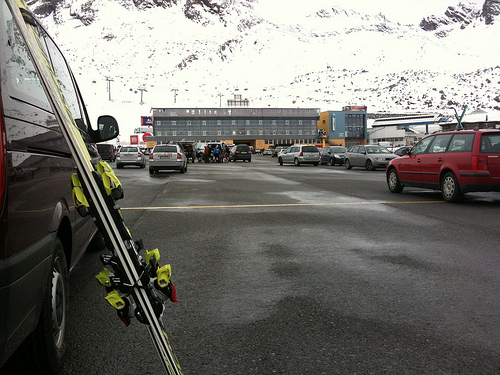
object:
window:
[447, 132, 476, 152]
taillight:
[176, 152, 183, 162]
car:
[148, 144, 187, 174]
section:
[234, 219, 407, 330]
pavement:
[83, 161, 483, 373]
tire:
[441, 172, 465, 204]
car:
[386, 129, 500, 204]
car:
[277, 145, 321, 166]